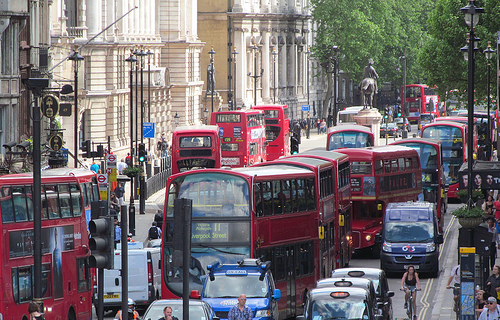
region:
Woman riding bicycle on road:
[398, 262, 427, 317]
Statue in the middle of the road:
[326, 53, 398, 128]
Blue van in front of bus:
[195, 251, 275, 319]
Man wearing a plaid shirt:
[226, 292, 255, 319]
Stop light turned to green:
[133, 133, 152, 217]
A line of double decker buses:
[149, 104, 462, 309]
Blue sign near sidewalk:
[137, 115, 164, 178]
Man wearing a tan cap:
[478, 291, 497, 316]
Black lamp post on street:
[437, 1, 498, 203]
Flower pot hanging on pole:
[448, 191, 488, 234]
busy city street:
[2, 80, 499, 319]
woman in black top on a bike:
[398, 259, 423, 319]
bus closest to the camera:
[1, 165, 113, 318]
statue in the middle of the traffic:
[355, 53, 385, 110]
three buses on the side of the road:
[166, 94, 296, 189]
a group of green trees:
[305, 0, 495, 125]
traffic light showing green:
[133, 137, 149, 163]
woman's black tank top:
[405, 272, 417, 287]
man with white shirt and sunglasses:
[473, 294, 498, 319]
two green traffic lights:
[381, 98, 408, 125]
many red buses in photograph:
[35, 42, 457, 317]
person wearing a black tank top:
[394, 251, 426, 315]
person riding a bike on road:
[390, 255, 430, 317]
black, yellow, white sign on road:
[448, 232, 472, 314]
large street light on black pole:
[22, 60, 64, 318]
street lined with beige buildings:
[5, 11, 367, 148]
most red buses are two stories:
[82, 81, 489, 316]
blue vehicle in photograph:
[192, 255, 260, 316]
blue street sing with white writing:
[115, 97, 193, 159]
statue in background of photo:
[337, 47, 407, 142]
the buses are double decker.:
[167, 95, 296, 177]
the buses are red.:
[162, 93, 297, 174]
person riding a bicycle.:
[397, 263, 425, 318]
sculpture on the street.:
[348, 52, 387, 134]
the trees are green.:
[307, 0, 498, 111]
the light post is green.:
[450, 1, 489, 206]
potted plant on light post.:
[453, 188, 484, 230]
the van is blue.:
[195, 255, 282, 318]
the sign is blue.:
[138, 113, 155, 140]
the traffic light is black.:
[78, 202, 120, 277]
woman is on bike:
[392, 264, 429, 319]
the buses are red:
[171, 118, 336, 271]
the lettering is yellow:
[196, 223, 229, 243]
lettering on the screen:
[192, 220, 246, 245]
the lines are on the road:
[422, 275, 433, 319]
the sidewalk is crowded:
[457, 219, 499, 314]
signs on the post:
[459, 227, 476, 316]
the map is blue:
[461, 283, 475, 318]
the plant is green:
[454, 204, 486, 222]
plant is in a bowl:
[455, 204, 485, 226]